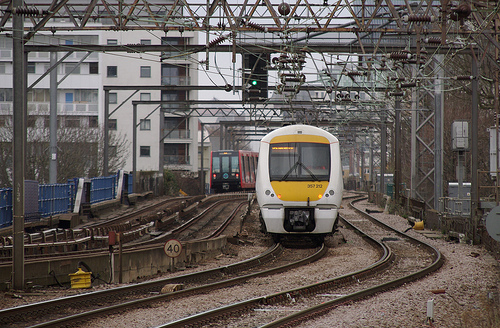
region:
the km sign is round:
[152, 224, 246, 296]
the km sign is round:
[147, 225, 199, 273]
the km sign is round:
[135, 203, 286, 320]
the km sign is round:
[115, 196, 200, 282]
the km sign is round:
[101, 170, 251, 312]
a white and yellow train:
[253, 119, 343, 241]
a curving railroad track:
[156, 173, 443, 327]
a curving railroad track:
[0, 225, 325, 325]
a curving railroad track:
[138, 191, 252, 242]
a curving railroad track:
[101, 186, 183, 230]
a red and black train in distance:
[205, 142, 258, 192]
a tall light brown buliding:
[10, 16, 195, 173]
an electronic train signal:
[240, 48, 267, 104]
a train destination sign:
[268, 144, 293, 151]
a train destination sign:
[215, 149, 234, 156]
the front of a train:
[253, 120, 342, 245]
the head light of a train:
[261, 184, 272, 199]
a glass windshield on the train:
[269, 137, 331, 184]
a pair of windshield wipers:
[276, 157, 320, 184]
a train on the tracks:
[201, 142, 265, 192]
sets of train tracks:
[0, 185, 451, 324]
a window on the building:
[134, 141, 154, 162]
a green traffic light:
[250, 76, 262, 88]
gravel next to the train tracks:
[278, 191, 494, 326]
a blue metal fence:
[0, 167, 141, 227]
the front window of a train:
[266, 140, 331, 183]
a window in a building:
[100, 61, 122, 79]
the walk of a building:
[61, 92, 95, 118]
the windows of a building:
[103, 60, 153, 82]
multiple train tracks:
[240, 256, 351, 311]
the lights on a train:
[261, 185, 272, 198]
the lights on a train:
[320, 186, 333, 197]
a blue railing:
[91, 176, 123, 203]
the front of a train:
[207, 149, 245, 192]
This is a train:
[248, 115, 353, 250]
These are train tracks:
[174, 252, 413, 322]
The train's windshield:
[266, 139, 337, 185]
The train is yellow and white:
[253, 122, 350, 237]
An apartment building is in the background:
[0, 22, 203, 177]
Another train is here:
[206, 136, 256, 196]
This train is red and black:
[208, 145, 256, 192]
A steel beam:
[6, 51, 40, 290]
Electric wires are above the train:
[202, 12, 442, 146]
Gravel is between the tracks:
[171, 264, 313, 309]